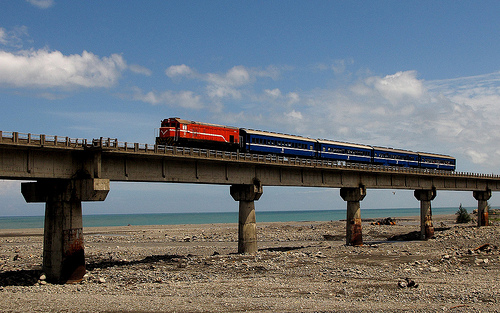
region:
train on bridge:
[146, 109, 461, 173]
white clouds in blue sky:
[7, 10, 59, 72]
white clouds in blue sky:
[401, 65, 422, 77]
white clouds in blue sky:
[394, 20, 427, 30]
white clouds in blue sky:
[409, 49, 433, 86]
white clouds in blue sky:
[319, 90, 361, 132]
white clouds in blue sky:
[132, 58, 196, 85]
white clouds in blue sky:
[279, 68, 319, 93]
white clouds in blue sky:
[383, 62, 413, 94]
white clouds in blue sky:
[217, 34, 272, 86]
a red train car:
[148, 115, 240, 151]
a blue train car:
[238, 128, 319, 158]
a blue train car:
[313, 134, 373, 163]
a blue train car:
[370, 143, 418, 168]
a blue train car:
[415, 151, 457, 173]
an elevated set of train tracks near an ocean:
[0, 112, 496, 287]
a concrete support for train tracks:
[20, 179, 112, 284]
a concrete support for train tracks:
[226, 181, 270, 260]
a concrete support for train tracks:
[340, 183, 367, 246]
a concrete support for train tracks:
[413, 188, 440, 241]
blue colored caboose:
[415, 149, 469, 170]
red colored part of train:
[148, 112, 243, 155]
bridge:
[5, 167, 450, 297]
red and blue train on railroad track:
[41, 88, 498, 188]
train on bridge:
[10, 119, 471, 191]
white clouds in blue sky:
[27, 34, 240, 112]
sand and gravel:
[146, 224, 245, 252]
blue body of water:
[154, 212, 206, 224]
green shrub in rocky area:
[453, 202, 475, 232]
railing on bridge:
[55, 138, 115, 148]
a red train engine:
[156, 113, 244, 150]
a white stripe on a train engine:
[169, 128, 229, 143]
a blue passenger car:
[240, 126, 319, 159]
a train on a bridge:
[153, 111, 456, 171]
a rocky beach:
[2, 211, 497, 312]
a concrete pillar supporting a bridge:
[230, 183, 261, 254]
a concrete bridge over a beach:
[1, 129, 499, 190]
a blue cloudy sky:
[0, 0, 497, 213]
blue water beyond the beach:
[0, 204, 499, 226]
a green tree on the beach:
[454, 203, 469, 223]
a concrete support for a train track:
[14, 179, 108, 281]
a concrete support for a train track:
[228, 184, 262, 256]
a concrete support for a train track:
[337, 184, 367, 246]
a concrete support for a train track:
[410, 189, 437, 241]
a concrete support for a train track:
[471, 190, 492, 229]